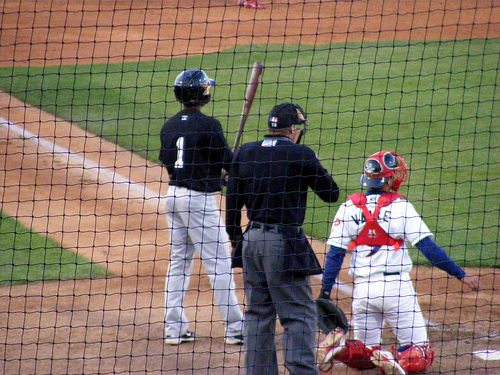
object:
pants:
[235, 221, 317, 373]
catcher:
[313, 149, 481, 375]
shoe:
[163, 328, 197, 346]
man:
[224, 100, 340, 375]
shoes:
[313, 326, 349, 370]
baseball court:
[0, 0, 499, 374]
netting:
[0, 0, 499, 374]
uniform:
[156, 107, 244, 338]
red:
[372, 235, 388, 248]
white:
[396, 279, 414, 297]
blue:
[415, 238, 455, 272]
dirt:
[0, 0, 498, 374]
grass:
[0, 37, 499, 270]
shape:
[347, 191, 404, 252]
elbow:
[315, 180, 341, 205]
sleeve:
[298, 143, 340, 203]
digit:
[173, 135, 185, 170]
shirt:
[158, 107, 233, 192]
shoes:
[367, 349, 409, 374]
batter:
[156, 67, 246, 347]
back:
[341, 192, 411, 278]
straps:
[367, 190, 398, 218]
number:
[170, 136, 185, 171]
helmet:
[170, 67, 217, 108]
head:
[172, 67, 217, 111]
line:
[0, 115, 437, 331]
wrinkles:
[185, 204, 224, 246]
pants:
[160, 185, 245, 340]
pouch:
[276, 224, 324, 279]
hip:
[239, 225, 301, 270]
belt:
[243, 219, 305, 237]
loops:
[244, 219, 305, 239]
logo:
[258, 137, 280, 149]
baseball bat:
[216, 60, 263, 187]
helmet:
[356, 149, 409, 190]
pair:
[240, 219, 320, 374]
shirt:
[223, 134, 339, 247]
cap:
[265, 101, 308, 130]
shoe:
[222, 330, 246, 346]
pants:
[347, 270, 429, 350]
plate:
[471, 348, 500, 362]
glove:
[311, 296, 354, 336]